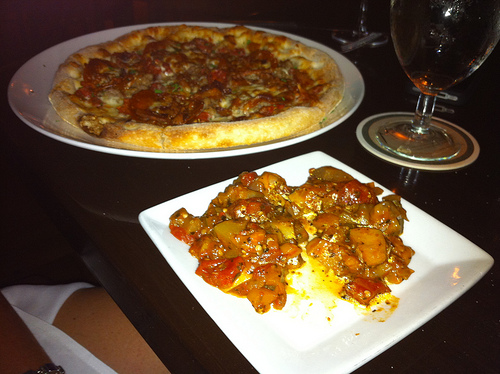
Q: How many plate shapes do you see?
A: 2.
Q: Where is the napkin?
A: On the left.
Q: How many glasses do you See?
A: 1.